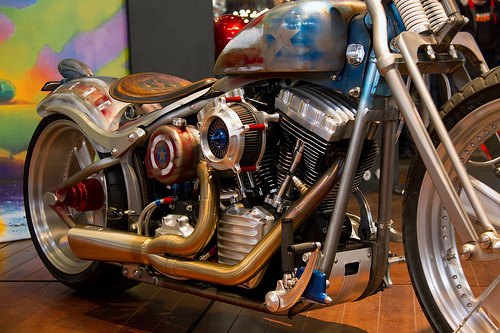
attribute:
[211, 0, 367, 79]
gas tank — custom, painted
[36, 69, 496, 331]
motorcycle — body 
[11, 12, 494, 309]
motorbike — metal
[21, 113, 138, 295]
wheel — back 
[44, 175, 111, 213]
joint — red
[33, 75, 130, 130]
wheel cover — painted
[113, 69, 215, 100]
seat — brown, leather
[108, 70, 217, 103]
seat — brown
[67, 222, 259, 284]
tubing — brass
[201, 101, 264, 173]
air filter — red, blue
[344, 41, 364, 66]
bolt — shiny, metal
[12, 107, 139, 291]
wheel — large motorcycle